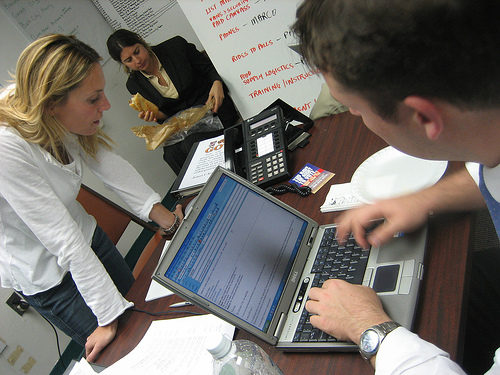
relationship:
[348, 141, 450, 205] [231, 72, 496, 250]
plate on top of desk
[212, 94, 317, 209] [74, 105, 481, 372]
phone on top of desk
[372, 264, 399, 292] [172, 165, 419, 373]
touch pad on laptop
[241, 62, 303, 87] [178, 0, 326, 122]
writing on erase board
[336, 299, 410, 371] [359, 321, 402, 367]
watch on watch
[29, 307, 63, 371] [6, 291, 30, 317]
cord on electric outlet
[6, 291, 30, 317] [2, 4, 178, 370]
electric outlet on wall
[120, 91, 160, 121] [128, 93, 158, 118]
hoagie on hoagie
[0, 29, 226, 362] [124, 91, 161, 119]
woman holding sandwich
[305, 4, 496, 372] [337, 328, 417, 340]
person wearing watch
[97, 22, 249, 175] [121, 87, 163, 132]
employee eating a burrito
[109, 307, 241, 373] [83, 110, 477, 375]
paper on top of desk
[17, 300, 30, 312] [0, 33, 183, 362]
plug behind blonde woman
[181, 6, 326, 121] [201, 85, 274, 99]
erase board with writing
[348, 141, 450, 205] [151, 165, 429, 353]
plate next to computer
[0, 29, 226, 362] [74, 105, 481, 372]
woman leaning over a desk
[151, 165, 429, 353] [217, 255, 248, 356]
computer switched on and open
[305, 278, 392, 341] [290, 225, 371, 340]
hands typing on a laptop keyboard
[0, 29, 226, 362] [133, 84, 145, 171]
woman eating a sandwich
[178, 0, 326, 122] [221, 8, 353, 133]
erase board with red and black writing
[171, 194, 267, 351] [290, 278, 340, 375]
email being composed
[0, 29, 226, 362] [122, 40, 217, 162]
woman wearing a black work suit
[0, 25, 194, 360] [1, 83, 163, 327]
blonde woman wearing a shirt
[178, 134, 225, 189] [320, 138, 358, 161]
binder of papers on corner of a desk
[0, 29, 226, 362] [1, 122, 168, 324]
woman wearing white shirt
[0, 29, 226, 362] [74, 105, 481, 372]
woman lean on a desk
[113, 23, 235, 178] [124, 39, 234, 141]
woman wearing black jacket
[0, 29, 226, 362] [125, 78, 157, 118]
woman eating a sandwich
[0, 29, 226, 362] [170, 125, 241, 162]
woman wearing black pants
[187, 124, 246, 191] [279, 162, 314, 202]
binder on a desk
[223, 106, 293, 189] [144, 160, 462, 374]
phone on a desk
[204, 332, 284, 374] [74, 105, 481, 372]
bottle on a desk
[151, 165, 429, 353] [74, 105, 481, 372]
computer on a desk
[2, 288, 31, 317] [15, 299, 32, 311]
electric outlet for a plug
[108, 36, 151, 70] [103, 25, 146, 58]
head with hair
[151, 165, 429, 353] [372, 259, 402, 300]
computer computers track pad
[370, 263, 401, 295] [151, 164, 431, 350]
touch pad on computer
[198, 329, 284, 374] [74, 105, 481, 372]
bottle on desk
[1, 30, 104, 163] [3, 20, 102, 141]
hair on head